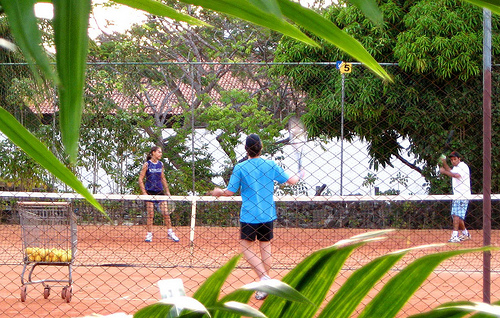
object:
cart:
[17, 198, 77, 307]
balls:
[34, 255, 42, 263]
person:
[216, 133, 298, 284]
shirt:
[228, 157, 289, 224]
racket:
[287, 114, 310, 188]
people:
[136, 142, 471, 246]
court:
[0, 222, 500, 318]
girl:
[141, 147, 179, 243]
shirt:
[140, 161, 170, 191]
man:
[437, 149, 478, 245]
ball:
[438, 154, 448, 161]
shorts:
[448, 195, 474, 220]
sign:
[341, 63, 352, 74]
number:
[341, 64, 351, 75]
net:
[7, 191, 500, 273]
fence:
[353, 62, 416, 228]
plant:
[5, 3, 136, 233]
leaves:
[49, 8, 92, 163]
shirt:
[446, 163, 478, 203]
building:
[25, 55, 412, 189]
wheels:
[20, 284, 28, 302]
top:
[3, 190, 201, 202]